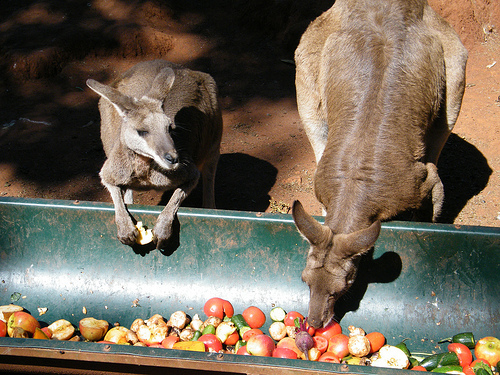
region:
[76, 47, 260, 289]
kangaroo with fruit in hand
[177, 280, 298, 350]
fruit in a tub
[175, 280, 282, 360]
red fruit mixed with other fruit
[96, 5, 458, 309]
big kangaroo and smaller one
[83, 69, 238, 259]
kangaroo looking to the right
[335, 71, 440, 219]
brown fur on kangaroo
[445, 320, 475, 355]
green food for the animals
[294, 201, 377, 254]
ears of the kangaroo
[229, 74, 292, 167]
brown dirt on ground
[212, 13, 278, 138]
shadow on ground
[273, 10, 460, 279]
this is a kangaroo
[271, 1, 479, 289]
the kangaroo is big in size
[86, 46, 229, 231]
baby kangaroo is beside the bigger one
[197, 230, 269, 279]
the basin is green in color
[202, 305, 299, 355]
these are fruits on the basin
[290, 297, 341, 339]
the kangaroo is feeding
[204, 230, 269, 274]
the basin is big in size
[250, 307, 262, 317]
the fruit is red in color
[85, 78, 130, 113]
this is the ear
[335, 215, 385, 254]
the ear is long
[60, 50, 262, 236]
kangaroo above fruit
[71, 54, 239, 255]
kangaroo holding a fruit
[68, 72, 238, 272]
kangaroo looking to its left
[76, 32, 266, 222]
smaller kangaroo next to bigger one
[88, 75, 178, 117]
ears of the kangaroo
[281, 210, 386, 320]
kangaroo eating something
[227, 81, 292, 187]
brown dirt next to giraffes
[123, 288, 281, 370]
food for the animals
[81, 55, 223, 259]
The smaller of the two kangaroos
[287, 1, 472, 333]
The larger of the two kangaroos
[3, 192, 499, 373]
The feeding trough of the kangaroos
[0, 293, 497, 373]
The food in the feeding trough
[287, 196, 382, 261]
The ears of the larger kangaroo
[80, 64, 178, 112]
The ears of the smaller kangaroo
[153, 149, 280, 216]
The shadow of the smaller kangaroo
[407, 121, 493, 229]
The shadow of the larger kangaroo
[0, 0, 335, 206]
The shade of a tree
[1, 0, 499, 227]
The dirt the kangaroos are standing on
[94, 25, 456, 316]
two kangaroos eating fruits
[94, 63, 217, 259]
a kangaroo holding a fruit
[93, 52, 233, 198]
a small kangaroo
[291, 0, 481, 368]
a big kangaroo eating fruits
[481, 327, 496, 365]
a red apple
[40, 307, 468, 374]
a bunch of fruits and veggies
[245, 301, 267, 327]
a red tomato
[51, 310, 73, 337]
an apple cut in two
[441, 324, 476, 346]
one half of a zucchini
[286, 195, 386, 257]
a kangaroo's ears